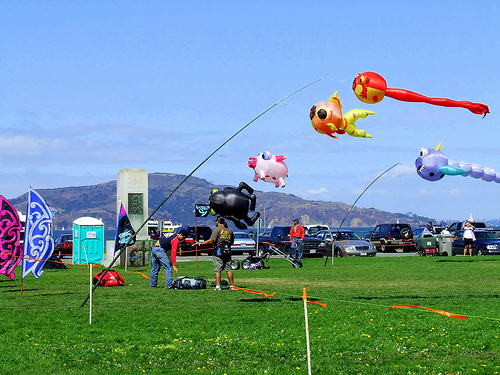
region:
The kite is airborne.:
[377, 132, 499, 219]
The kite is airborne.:
[346, 55, 499, 115]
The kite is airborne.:
[297, 84, 392, 146]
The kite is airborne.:
[233, 141, 345, 189]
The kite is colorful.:
[238, 140, 325, 192]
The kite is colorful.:
[298, 88, 389, 143]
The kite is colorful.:
[341, 56, 498, 118]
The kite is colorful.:
[397, 134, 499, 209]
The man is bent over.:
[144, 220, 197, 295]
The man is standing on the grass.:
[187, 211, 244, 307]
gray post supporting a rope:
[301, 288, 315, 373]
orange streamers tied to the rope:
[388, 303, 468, 323]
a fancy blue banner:
[22, 185, 54, 301]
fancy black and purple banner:
[1, 196, 23, 293]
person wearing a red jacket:
[288, 216, 309, 266]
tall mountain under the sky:
[9, 172, 446, 230]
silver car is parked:
[318, 228, 378, 256]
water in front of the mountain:
[326, 225, 375, 235]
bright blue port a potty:
[71, 215, 105, 264]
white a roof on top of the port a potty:
[73, 215, 103, 225]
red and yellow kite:
[359, 65, 390, 103]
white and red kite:
[233, 131, 294, 195]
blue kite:
[403, 147, 464, 188]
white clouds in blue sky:
[61, 45, 88, 72]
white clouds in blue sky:
[31, 44, 95, 98]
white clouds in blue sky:
[179, 77, 199, 94]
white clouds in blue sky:
[69, 55, 109, 87]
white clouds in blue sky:
[233, 23, 260, 53]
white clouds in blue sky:
[74, 53, 134, 101]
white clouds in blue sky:
[110, 77, 161, 125]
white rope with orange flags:
[0, 256, 496, 371]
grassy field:
[0, 250, 497, 373]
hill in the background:
[0, 172, 450, 230]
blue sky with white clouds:
[0, 3, 497, 220]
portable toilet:
[71, 216, 106, 265]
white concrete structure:
[106, 168, 148, 265]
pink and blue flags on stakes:
[0, 186, 54, 296]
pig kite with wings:
[246, 150, 287, 185]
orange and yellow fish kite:
[306, 92, 373, 140]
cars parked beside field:
[51, 219, 499, 259]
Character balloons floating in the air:
[190, 68, 498, 229]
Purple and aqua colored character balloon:
[415, 140, 496, 181]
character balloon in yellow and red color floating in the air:
[350, 70, 490, 115]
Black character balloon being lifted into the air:
[188, 182, 258, 232]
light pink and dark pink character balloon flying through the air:
[245, 145, 287, 187]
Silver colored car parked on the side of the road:
[317, 227, 377, 253]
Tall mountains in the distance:
[2, 175, 493, 236]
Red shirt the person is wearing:
[285, 222, 305, 239]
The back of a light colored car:
[228, 228, 255, 251]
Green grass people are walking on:
[0, 252, 499, 373]